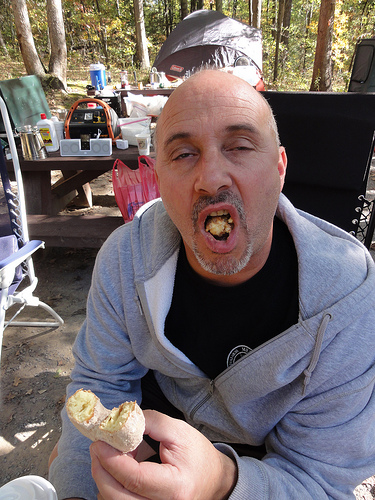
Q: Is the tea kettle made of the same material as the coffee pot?
A: Yes, both the tea kettle and the coffee pot are made of metal.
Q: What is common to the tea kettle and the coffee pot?
A: The material, both the tea kettle and the coffee pot are metallic.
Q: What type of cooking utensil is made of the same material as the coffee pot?
A: The tea kettle is made of the same material as the coffee pot.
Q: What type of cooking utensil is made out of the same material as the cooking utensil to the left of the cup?
A: The tea kettle is made of the same material as the coffee pot.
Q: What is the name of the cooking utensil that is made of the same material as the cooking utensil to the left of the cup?
A: The cooking utensil is a tea kettle.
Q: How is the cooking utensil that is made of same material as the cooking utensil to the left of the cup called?
A: The cooking utensil is a tea kettle.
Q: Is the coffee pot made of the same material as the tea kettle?
A: Yes, both the coffee pot and the tea kettle are made of metal.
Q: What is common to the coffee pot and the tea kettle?
A: The material, both the coffee pot and the tea kettle are metallic.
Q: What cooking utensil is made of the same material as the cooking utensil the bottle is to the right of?
A: The coffee pot is made of the same material as the tea kettle.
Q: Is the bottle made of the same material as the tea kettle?
A: No, the bottle is made of plastic and the tea kettle is made of metal.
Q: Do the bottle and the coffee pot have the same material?
A: No, the bottle is made of plastic and the coffee pot is made of metal.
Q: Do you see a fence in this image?
A: No, there are no fences.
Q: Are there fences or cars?
A: No, there are no fences or cars.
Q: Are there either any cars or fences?
A: No, there are no fences or cars.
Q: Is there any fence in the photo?
A: No, there are no fences.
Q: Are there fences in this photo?
A: No, there are no fences.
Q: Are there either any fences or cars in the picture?
A: No, there are no fences or cars.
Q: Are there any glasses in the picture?
A: No, there are no glasses.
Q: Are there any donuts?
A: Yes, there is a donut.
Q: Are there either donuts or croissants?
A: Yes, there is a donut.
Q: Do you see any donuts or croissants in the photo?
A: Yes, there is a donut.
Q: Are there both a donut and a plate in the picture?
A: No, there is a donut but no plates.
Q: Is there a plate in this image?
A: No, there are no plates.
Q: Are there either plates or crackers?
A: No, there are no plates or crackers.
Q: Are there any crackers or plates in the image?
A: No, there are no plates or crackers.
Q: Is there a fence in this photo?
A: No, there are no fences.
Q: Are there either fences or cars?
A: No, there are no fences or cars.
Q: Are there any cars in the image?
A: No, there are no cars.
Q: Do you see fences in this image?
A: No, there are no fences.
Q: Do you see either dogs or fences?
A: No, there are no fences or dogs.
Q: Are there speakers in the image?
A: Yes, there are speakers.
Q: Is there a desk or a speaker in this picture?
A: Yes, there are speakers.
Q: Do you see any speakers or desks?
A: Yes, there are speakers.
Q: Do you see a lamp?
A: No, there are no lamps.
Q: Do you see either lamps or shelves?
A: No, there are no lamps or shelves.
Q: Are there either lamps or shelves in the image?
A: No, there are no lamps or shelves.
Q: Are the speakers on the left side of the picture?
A: Yes, the speakers are on the left of the image.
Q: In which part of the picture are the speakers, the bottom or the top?
A: The speakers are in the top of the image.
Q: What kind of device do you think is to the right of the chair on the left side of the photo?
A: The devices are speakers.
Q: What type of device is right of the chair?
A: The devices are speakers.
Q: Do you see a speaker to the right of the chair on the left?
A: Yes, there are speakers to the right of the chair.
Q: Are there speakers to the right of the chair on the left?
A: Yes, there are speakers to the right of the chair.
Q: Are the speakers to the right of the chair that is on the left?
A: Yes, the speakers are to the right of the chair.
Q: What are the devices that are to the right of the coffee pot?
A: The devices are speakers.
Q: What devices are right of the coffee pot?
A: The devices are speakers.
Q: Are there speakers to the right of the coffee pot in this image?
A: Yes, there are speakers to the right of the coffee pot.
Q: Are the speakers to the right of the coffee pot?
A: Yes, the speakers are to the right of the coffee pot.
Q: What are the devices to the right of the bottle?
A: The devices are speakers.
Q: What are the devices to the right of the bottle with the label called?
A: The devices are speakers.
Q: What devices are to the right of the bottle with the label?
A: The devices are speakers.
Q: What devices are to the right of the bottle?
A: The devices are speakers.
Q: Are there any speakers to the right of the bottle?
A: Yes, there are speakers to the right of the bottle.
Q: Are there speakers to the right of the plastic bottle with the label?
A: Yes, there are speakers to the right of the bottle.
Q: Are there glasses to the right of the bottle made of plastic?
A: No, there are speakers to the right of the bottle.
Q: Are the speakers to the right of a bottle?
A: Yes, the speakers are to the right of a bottle.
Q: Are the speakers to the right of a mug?
A: No, the speakers are to the right of a bottle.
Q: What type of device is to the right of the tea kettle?
A: The devices are speakers.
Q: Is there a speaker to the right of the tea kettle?
A: Yes, there are speakers to the right of the tea kettle.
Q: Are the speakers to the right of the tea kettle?
A: Yes, the speakers are to the right of the tea kettle.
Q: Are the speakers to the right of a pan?
A: No, the speakers are to the right of the tea kettle.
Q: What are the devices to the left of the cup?
A: The devices are speakers.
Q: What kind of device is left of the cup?
A: The devices are speakers.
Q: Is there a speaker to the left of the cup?
A: Yes, there are speakers to the left of the cup.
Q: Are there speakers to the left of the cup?
A: Yes, there are speakers to the left of the cup.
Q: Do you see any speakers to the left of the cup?
A: Yes, there are speakers to the left of the cup.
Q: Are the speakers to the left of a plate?
A: No, the speakers are to the left of the cup.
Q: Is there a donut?
A: Yes, there are donuts.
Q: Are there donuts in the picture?
A: Yes, there are donuts.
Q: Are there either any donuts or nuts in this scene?
A: Yes, there are donuts.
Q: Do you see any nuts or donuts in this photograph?
A: Yes, there are donuts.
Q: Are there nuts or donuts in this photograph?
A: Yes, there are donuts.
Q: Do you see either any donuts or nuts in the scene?
A: Yes, there are donuts.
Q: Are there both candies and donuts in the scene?
A: No, there are donuts but no candies.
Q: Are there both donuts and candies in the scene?
A: No, there are donuts but no candies.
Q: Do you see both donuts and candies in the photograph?
A: No, there are donuts but no candies.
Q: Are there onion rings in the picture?
A: No, there are no onion rings.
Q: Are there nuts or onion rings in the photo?
A: No, there are no onion rings or nuts.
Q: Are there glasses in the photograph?
A: No, there are no glasses.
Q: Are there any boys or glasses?
A: No, there are no glasses or boys.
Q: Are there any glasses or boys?
A: No, there are no glasses or boys.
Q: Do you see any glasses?
A: No, there are no glasses.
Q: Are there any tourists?
A: No, there are no tourists.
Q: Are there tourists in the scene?
A: No, there are no tourists.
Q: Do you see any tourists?
A: No, there are no tourists.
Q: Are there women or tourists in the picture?
A: No, there are no tourists or women.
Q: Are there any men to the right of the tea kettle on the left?
A: Yes, there is a man to the right of the tea kettle.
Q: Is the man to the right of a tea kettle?
A: Yes, the man is to the right of a tea kettle.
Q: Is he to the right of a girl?
A: No, the man is to the right of a tea kettle.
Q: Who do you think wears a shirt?
A: The man wears a shirt.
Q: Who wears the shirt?
A: The man wears a shirt.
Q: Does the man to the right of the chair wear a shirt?
A: Yes, the man wears a shirt.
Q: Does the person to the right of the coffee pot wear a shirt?
A: Yes, the man wears a shirt.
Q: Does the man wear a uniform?
A: No, the man wears a shirt.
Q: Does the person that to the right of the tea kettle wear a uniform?
A: No, the man wears a shirt.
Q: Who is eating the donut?
A: The man is eating the donut.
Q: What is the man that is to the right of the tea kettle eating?
A: The man is eating a donut.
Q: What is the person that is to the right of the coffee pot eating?
A: The man is eating a donut.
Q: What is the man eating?
A: The man is eating a donut.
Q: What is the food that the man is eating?
A: The food is a donut.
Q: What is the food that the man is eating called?
A: The food is a donut.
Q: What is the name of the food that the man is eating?
A: The food is a donut.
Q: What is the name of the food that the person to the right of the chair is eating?
A: The food is a donut.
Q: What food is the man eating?
A: The man is eating a donut.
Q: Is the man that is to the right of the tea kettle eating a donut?
A: Yes, the man is eating a donut.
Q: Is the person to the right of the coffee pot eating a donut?
A: Yes, the man is eating a donut.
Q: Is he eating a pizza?
A: No, the man is eating a donut.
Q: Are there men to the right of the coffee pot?
A: Yes, there is a man to the right of the coffee pot.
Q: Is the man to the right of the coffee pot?
A: Yes, the man is to the right of the coffee pot.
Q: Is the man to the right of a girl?
A: No, the man is to the right of the coffee pot.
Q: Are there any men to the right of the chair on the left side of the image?
A: Yes, there is a man to the right of the chair.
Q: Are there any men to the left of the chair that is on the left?
A: No, the man is to the right of the chair.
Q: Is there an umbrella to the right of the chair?
A: No, there is a man to the right of the chair.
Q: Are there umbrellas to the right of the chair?
A: No, there is a man to the right of the chair.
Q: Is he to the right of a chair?
A: Yes, the man is to the right of a chair.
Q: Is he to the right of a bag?
A: No, the man is to the right of a chair.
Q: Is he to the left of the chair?
A: No, the man is to the right of the chair.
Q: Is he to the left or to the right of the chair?
A: The man is to the right of the chair.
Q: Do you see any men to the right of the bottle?
A: Yes, there is a man to the right of the bottle.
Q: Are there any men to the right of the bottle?
A: Yes, there is a man to the right of the bottle.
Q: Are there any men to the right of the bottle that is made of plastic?
A: Yes, there is a man to the right of the bottle.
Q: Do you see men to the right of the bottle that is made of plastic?
A: Yes, there is a man to the right of the bottle.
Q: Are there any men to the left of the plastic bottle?
A: No, the man is to the right of the bottle.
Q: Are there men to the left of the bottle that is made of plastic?
A: No, the man is to the right of the bottle.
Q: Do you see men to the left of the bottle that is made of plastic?
A: No, the man is to the right of the bottle.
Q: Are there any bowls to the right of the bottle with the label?
A: No, there is a man to the right of the bottle.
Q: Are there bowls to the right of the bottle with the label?
A: No, there is a man to the right of the bottle.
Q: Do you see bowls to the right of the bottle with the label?
A: No, there is a man to the right of the bottle.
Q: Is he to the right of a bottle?
A: Yes, the man is to the right of a bottle.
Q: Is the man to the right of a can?
A: No, the man is to the right of a bottle.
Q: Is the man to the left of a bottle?
A: No, the man is to the right of a bottle.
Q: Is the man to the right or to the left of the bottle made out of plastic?
A: The man is to the right of the bottle.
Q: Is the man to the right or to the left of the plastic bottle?
A: The man is to the right of the bottle.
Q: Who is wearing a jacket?
A: The man is wearing a jacket.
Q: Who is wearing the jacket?
A: The man is wearing a jacket.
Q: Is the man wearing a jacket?
A: Yes, the man is wearing a jacket.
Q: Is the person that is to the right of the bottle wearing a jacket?
A: Yes, the man is wearing a jacket.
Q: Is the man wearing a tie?
A: No, the man is wearing a jacket.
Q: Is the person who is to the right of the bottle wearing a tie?
A: No, the man is wearing a jacket.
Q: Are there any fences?
A: No, there are no fences.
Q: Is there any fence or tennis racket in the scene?
A: No, there are no fences or rackets.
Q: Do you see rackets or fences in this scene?
A: No, there are no fences or rackets.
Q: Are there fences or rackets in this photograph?
A: No, there are no fences or rackets.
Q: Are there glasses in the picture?
A: No, there are no glasses.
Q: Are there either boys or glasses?
A: No, there are no glasses or boys.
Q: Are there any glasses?
A: No, there are no glasses.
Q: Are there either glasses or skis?
A: No, there are no glasses or skis.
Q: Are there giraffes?
A: No, there are no giraffes.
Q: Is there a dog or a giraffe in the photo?
A: No, there are no giraffes or dogs.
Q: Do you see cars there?
A: No, there are no cars.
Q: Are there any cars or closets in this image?
A: No, there are no cars or closets.